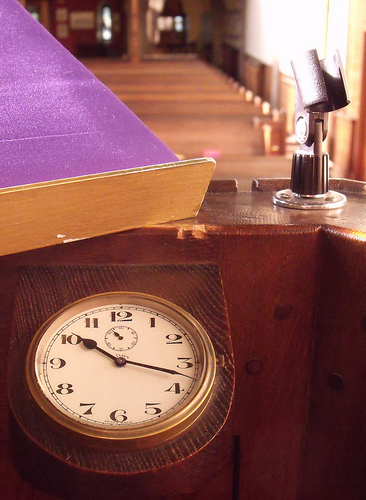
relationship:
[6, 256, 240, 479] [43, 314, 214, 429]
clock reads 10:17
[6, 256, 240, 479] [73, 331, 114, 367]
clock has a hand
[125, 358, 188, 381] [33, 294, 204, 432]
hand tells minutes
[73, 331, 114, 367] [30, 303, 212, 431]
hand tells hours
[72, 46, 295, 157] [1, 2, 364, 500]
pews are in a church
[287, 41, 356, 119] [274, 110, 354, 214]
microphone on a stand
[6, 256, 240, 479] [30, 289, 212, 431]
clock has a face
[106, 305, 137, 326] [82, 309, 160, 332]
12 between 11 and 1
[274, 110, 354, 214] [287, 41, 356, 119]
stand holds microphone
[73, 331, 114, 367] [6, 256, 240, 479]
hand on clock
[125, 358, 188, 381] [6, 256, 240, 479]
hand on clock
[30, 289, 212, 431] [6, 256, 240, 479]
face on clock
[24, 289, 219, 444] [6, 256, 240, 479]
rim around clock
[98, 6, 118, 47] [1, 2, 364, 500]
window in church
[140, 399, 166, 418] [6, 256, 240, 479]
number on clock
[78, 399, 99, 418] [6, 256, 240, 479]
number on clock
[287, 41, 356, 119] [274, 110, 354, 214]
microphone in a stand